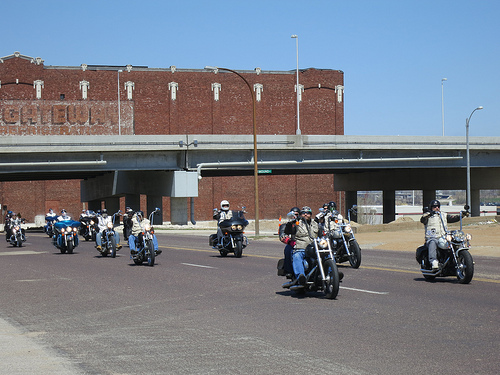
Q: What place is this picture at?
A: It is at the road.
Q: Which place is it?
A: It is a road.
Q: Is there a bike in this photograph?
A: Yes, there is a bike.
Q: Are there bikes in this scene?
A: Yes, there is a bike.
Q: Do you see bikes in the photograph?
A: Yes, there is a bike.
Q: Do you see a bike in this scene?
A: Yes, there is a bike.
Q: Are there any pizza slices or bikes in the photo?
A: Yes, there is a bike.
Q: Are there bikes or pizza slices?
A: Yes, there is a bike.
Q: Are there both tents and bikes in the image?
A: No, there is a bike but no tents.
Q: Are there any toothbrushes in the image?
A: No, there are no toothbrushes.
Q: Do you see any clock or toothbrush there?
A: No, there are no toothbrushes or clocks.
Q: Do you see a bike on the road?
A: Yes, there is a bike on the road.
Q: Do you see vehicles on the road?
A: No, there is a bike on the road.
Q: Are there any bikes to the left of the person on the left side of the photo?
A: Yes, there is a bike to the left of the person.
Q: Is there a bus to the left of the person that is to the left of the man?
A: No, there is a bike to the left of the person.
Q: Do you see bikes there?
A: Yes, there is a bike.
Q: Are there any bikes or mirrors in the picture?
A: Yes, there is a bike.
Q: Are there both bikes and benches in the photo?
A: No, there is a bike but no benches.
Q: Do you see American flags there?
A: No, there are no American flags.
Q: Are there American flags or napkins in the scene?
A: No, there are no American flags or napkins.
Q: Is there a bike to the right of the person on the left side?
A: Yes, there is a bike to the right of the person.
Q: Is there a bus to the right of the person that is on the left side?
A: No, there is a bike to the right of the person.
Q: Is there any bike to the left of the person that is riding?
A: Yes, there is a bike to the left of the person.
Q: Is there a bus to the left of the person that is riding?
A: No, there is a bike to the left of the person.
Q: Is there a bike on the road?
A: Yes, there is a bike on the road.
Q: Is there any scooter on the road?
A: No, there is a bike on the road.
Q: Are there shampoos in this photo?
A: No, there are no shampoos.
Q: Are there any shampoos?
A: No, there are no shampoos.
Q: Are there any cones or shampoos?
A: No, there are no shampoos or cones.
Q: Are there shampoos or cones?
A: No, there are no shampoos or cones.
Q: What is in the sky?
A: The clouds are in the sky.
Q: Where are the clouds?
A: The clouds are in the sky.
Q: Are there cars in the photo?
A: No, there are no cars.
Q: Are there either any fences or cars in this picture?
A: No, there are no cars or fences.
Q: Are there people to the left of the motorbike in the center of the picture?
A: Yes, there is a person to the left of the motorcycle.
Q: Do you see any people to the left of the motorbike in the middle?
A: Yes, there is a person to the left of the motorcycle.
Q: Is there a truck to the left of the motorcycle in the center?
A: No, there is a person to the left of the motorcycle.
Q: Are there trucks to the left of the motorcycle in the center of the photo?
A: No, there is a person to the left of the motorcycle.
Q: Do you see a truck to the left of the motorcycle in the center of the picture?
A: No, there is a person to the left of the motorcycle.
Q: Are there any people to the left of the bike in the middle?
A: Yes, there is a person to the left of the bike.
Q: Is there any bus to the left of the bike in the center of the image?
A: No, there is a person to the left of the bike.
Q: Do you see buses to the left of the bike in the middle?
A: No, there is a person to the left of the bike.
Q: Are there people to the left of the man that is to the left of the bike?
A: Yes, there is a person to the left of the man.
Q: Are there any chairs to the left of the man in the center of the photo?
A: No, there is a person to the left of the man.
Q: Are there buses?
A: No, there are no buses.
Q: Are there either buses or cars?
A: No, there are no buses or cars.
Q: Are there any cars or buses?
A: No, there are no buses or cars.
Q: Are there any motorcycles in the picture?
A: Yes, there is a motorcycle.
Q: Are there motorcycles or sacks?
A: Yes, there is a motorcycle.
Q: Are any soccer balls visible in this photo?
A: No, there are no soccer balls.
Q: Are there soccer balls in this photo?
A: No, there are no soccer balls.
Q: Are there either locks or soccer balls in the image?
A: No, there are no soccer balls or locks.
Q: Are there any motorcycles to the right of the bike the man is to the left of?
A: Yes, there is a motorcycle to the right of the bike.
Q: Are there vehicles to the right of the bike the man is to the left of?
A: No, there is a motorcycle to the right of the bike.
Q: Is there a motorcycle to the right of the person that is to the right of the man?
A: Yes, there is a motorcycle to the right of the person.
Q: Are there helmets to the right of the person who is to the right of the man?
A: No, there is a motorcycle to the right of the person.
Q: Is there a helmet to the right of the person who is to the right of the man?
A: No, there is a motorcycle to the right of the person.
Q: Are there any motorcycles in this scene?
A: Yes, there is a motorcycle.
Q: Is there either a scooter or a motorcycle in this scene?
A: Yes, there is a motorcycle.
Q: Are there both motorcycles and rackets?
A: No, there is a motorcycle but no rackets.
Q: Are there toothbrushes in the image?
A: No, there are no toothbrushes.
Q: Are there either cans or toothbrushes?
A: No, there are no toothbrushes or cans.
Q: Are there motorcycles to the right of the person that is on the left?
A: Yes, there is a motorcycle to the right of the person.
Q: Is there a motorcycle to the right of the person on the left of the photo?
A: Yes, there is a motorcycle to the right of the person.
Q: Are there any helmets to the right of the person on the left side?
A: No, there is a motorcycle to the right of the person.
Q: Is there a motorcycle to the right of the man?
A: Yes, there is a motorcycle to the right of the man.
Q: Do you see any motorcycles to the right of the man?
A: Yes, there is a motorcycle to the right of the man.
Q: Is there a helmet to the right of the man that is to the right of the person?
A: No, there is a motorcycle to the right of the man.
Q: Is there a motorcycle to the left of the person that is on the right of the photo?
A: Yes, there is a motorcycle to the left of the person.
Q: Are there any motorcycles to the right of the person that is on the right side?
A: No, the motorcycle is to the left of the person.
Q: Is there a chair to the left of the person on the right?
A: No, there is a motorcycle to the left of the person.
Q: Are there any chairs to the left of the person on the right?
A: No, there is a motorcycle to the left of the person.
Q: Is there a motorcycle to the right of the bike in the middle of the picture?
A: Yes, there is a motorcycle to the right of the bike.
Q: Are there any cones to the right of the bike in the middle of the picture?
A: No, there is a motorcycle to the right of the bike.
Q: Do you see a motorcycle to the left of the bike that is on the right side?
A: Yes, there is a motorcycle to the left of the bike.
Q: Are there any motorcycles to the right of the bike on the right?
A: No, the motorcycle is to the left of the bike.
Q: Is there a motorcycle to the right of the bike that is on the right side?
A: No, the motorcycle is to the left of the bike.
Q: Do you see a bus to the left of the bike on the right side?
A: No, there is a motorcycle to the left of the bike.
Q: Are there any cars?
A: No, there are no cars.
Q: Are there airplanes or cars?
A: No, there are no cars or airplanes.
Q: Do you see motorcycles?
A: Yes, there is a motorcycle.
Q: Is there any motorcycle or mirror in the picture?
A: Yes, there is a motorcycle.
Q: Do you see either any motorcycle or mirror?
A: Yes, there is a motorcycle.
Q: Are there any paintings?
A: No, there are no paintings.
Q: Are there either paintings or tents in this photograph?
A: No, there are no paintings or tents.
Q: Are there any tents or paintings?
A: No, there are no paintings or tents.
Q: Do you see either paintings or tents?
A: No, there are no paintings or tents.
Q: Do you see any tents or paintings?
A: No, there are no paintings or tents.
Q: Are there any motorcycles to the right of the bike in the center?
A: Yes, there is a motorcycle to the right of the bike.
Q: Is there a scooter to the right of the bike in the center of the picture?
A: No, there is a motorcycle to the right of the bike.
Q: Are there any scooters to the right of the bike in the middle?
A: No, there is a motorcycle to the right of the bike.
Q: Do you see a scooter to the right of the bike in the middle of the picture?
A: No, there is a motorcycle to the right of the bike.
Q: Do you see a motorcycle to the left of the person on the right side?
A: Yes, there is a motorcycle to the left of the person.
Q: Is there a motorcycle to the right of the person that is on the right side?
A: No, the motorcycle is to the left of the person.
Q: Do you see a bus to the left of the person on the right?
A: No, there is a motorcycle to the left of the person.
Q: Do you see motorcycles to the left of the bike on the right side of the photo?
A: Yes, there is a motorcycle to the left of the bike.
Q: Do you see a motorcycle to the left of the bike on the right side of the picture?
A: Yes, there is a motorcycle to the left of the bike.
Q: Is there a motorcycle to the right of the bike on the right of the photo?
A: No, the motorcycle is to the left of the bike.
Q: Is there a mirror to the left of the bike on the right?
A: No, there is a motorcycle to the left of the bike.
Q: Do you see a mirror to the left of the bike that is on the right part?
A: No, there is a motorcycle to the left of the bike.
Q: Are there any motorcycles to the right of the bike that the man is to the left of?
A: Yes, there is a motorcycle to the right of the bike.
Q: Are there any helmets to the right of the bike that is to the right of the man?
A: No, there is a motorcycle to the right of the bike.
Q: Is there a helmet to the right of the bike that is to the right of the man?
A: No, there is a motorcycle to the right of the bike.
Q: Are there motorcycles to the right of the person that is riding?
A: Yes, there is a motorcycle to the right of the person.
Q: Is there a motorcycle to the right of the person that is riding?
A: Yes, there is a motorcycle to the right of the person.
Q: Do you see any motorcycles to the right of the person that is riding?
A: Yes, there is a motorcycle to the right of the person.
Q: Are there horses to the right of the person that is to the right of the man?
A: No, there is a motorcycle to the right of the person.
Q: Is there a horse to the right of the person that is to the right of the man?
A: No, there is a motorcycle to the right of the person.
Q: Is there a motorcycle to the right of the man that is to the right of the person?
A: Yes, there is a motorcycle to the right of the man.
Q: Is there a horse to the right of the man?
A: No, there is a motorcycle to the right of the man.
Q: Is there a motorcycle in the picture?
A: Yes, there is a motorcycle.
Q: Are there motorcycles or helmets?
A: Yes, there is a motorcycle.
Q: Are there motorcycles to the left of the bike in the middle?
A: Yes, there is a motorcycle to the left of the bike.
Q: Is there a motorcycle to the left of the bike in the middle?
A: Yes, there is a motorcycle to the left of the bike.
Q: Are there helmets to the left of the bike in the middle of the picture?
A: No, there is a motorcycle to the left of the bike.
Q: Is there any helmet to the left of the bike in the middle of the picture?
A: No, there is a motorcycle to the left of the bike.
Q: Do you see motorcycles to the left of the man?
A: Yes, there is a motorcycle to the left of the man.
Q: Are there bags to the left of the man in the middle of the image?
A: No, there is a motorcycle to the left of the man.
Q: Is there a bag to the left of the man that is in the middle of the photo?
A: No, there is a motorcycle to the left of the man.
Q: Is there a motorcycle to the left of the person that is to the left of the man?
A: Yes, there is a motorcycle to the left of the person.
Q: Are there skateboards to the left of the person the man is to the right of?
A: No, there is a motorcycle to the left of the person.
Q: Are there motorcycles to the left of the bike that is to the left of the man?
A: Yes, there is a motorcycle to the left of the bike.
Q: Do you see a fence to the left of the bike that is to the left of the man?
A: No, there is a motorcycle to the left of the bike.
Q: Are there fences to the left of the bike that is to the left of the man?
A: No, there is a motorcycle to the left of the bike.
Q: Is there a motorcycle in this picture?
A: Yes, there is a motorcycle.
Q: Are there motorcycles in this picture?
A: Yes, there is a motorcycle.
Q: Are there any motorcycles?
A: Yes, there is a motorcycle.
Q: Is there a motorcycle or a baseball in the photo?
A: Yes, there is a motorcycle.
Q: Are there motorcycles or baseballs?
A: Yes, there is a motorcycle.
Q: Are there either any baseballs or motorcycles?
A: Yes, there is a motorcycle.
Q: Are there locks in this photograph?
A: No, there are no locks.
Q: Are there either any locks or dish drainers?
A: No, there are no locks or dish drainers.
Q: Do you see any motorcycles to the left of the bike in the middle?
A: Yes, there is a motorcycle to the left of the bike.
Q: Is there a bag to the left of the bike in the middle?
A: No, there is a motorcycle to the left of the bike.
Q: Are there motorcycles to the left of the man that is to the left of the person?
A: Yes, there is a motorcycle to the left of the man.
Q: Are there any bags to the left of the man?
A: No, there is a motorcycle to the left of the man.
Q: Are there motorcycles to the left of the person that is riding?
A: Yes, there is a motorcycle to the left of the person.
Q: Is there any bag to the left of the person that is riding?
A: No, there is a motorcycle to the left of the person.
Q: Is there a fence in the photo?
A: No, there are no fences.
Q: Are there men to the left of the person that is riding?
A: Yes, there is a man to the left of the person.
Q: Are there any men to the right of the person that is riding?
A: No, the man is to the left of the person.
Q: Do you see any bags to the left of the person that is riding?
A: No, there is a man to the left of the person.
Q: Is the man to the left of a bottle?
A: No, the man is to the left of a person.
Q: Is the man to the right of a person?
A: No, the man is to the left of a person.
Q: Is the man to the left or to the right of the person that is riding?
A: The man is to the left of the person.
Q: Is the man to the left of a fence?
A: No, the man is to the left of a motorcycle.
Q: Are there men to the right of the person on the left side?
A: Yes, there is a man to the right of the person.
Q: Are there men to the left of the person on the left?
A: No, the man is to the right of the person.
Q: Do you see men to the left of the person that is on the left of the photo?
A: No, the man is to the right of the person.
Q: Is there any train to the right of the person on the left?
A: No, there is a man to the right of the person.